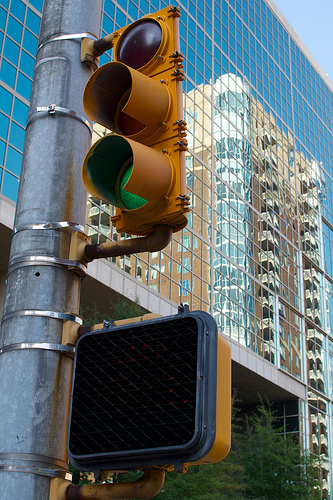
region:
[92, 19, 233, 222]
traffic light is green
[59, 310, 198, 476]
red do not walk sign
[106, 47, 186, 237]
yellow housing for traffic light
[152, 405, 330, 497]
green tree behind traffic light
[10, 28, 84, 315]
traffic light on grey pole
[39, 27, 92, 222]
metal clips on pole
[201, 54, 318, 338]
reflective windows on building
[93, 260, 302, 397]
concrete face on building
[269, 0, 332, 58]
blue and white sky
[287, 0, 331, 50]
sky overhead is clear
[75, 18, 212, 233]
row of three lights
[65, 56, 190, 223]
two yellow cones around the lights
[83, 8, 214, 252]
traffic light is shining green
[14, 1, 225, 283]
traffic light attached to a pole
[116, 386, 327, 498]
dark green tree tops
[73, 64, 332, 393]
reflection of a building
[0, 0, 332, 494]
building is covered in windows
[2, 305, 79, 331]
silver band around the pole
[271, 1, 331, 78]
bright blue sky with no clouds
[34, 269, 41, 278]
hole in the pole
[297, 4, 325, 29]
A blue color clear sky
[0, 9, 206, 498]
Metal pole with traffic signal lights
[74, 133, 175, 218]
Green color traffic signal light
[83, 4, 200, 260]
Yellow color box of the signal traffic lights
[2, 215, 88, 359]
Silver color metal clamp fixed with pole and traffic signal light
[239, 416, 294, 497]
Trees with green leaves and branches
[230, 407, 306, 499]
Tree near the building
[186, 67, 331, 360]
Reflection of the building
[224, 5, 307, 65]
Glass building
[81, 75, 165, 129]
Orange color traffic signal light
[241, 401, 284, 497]
A green color plant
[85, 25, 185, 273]
A signal light on a pole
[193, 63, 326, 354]
Reflection of another building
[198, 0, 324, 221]
A tall building on the side of the signal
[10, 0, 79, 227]
A silver color pole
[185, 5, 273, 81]
The building has square architecture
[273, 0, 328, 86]
Light blue color sky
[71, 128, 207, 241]
The green light is on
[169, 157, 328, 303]
Reflection of white and brown color building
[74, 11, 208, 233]
The signal is yellow in color